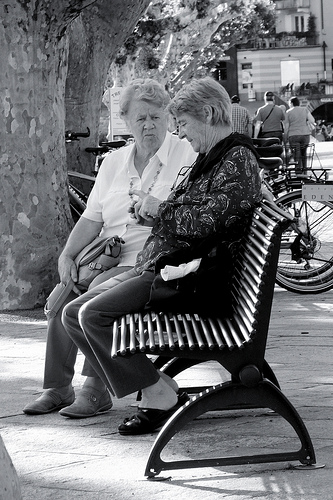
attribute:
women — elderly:
[71, 79, 251, 284]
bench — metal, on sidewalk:
[196, 206, 281, 409]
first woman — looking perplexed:
[34, 53, 173, 267]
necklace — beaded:
[121, 180, 165, 196]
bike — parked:
[265, 138, 332, 272]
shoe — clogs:
[108, 384, 181, 438]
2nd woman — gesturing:
[161, 86, 251, 343]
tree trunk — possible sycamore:
[3, 17, 76, 327]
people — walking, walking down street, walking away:
[224, 93, 308, 141]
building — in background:
[271, 11, 332, 55]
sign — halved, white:
[294, 180, 332, 201]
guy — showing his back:
[222, 93, 264, 138]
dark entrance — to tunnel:
[315, 104, 329, 112]